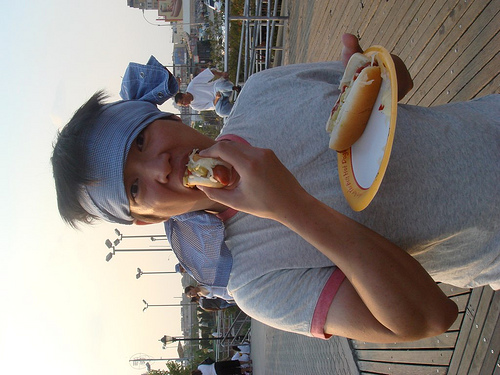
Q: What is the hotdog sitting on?
A: A plate.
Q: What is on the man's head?
A: A headband.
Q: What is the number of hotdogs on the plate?
A: One.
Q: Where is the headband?
A: On the man's head.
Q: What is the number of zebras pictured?
A: Zero.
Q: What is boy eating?
A: Hot dog.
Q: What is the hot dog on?
A: Plate.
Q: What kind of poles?
A: Street Lights.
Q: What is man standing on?
A: Wood.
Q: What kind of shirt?
A: Tshirt.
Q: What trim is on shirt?
A: Red.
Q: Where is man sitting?
A: Fence.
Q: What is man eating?
A: Burger.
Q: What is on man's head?
A: Bandana.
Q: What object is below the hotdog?
A: A plate.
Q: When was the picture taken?
A: During daytime.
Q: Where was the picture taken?
A: A city.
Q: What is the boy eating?
A: A hot dog.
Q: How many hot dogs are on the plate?
A: One.